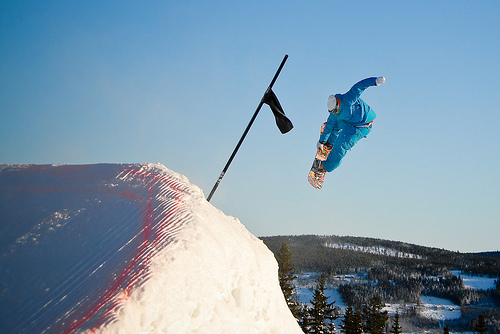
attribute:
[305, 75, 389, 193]
skier — doing trick in air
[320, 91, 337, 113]
hat — white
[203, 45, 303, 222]
pole — ski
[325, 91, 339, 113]
hat — white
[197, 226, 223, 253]
snow — white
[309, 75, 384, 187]
man — in air, blue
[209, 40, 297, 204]
pole — sticking in air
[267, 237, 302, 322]
tree — green, tall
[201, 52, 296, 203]
flag — black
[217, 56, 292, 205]
pole — black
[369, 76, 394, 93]
glove — white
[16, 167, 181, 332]
paint — red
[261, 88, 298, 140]
flag — black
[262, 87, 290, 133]
flag — black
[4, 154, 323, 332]
field — snowy